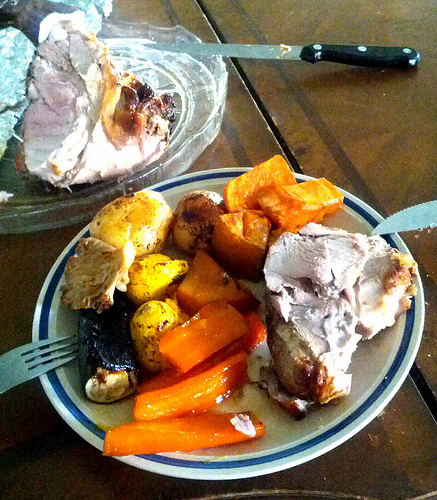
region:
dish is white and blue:
[15, 150, 433, 485]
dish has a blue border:
[26, 159, 435, 487]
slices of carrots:
[102, 304, 269, 458]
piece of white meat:
[252, 223, 413, 415]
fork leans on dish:
[5, 323, 81, 398]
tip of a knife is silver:
[369, 197, 435, 248]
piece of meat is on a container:
[0, 65, 227, 204]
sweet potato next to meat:
[206, 157, 341, 251]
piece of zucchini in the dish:
[67, 312, 146, 411]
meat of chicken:
[255, 217, 424, 419]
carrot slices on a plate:
[101, 306, 265, 463]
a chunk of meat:
[259, 220, 412, 410]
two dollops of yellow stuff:
[127, 250, 188, 359]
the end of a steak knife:
[363, 190, 434, 243]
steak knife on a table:
[139, 37, 423, 72]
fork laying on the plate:
[0, 324, 87, 391]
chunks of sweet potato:
[220, 148, 343, 253]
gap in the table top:
[232, 63, 291, 152]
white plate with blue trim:
[21, 166, 424, 480]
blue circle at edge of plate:
[26, 165, 423, 480]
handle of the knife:
[347, 39, 415, 79]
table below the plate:
[375, 431, 419, 464]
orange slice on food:
[154, 401, 227, 455]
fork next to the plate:
[29, 320, 95, 378]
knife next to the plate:
[347, 183, 420, 246]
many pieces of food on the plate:
[77, 168, 386, 375]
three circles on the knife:
[306, 31, 418, 79]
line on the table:
[399, 360, 432, 421]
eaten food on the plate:
[30, 12, 187, 155]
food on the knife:
[266, 33, 297, 69]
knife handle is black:
[292, 26, 431, 87]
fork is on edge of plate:
[0, 284, 102, 407]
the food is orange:
[154, 244, 251, 481]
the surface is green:
[1, 0, 432, 496]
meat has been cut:
[72, 284, 145, 408]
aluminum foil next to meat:
[2, 20, 53, 160]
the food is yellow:
[115, 252, 202, 375]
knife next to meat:
[350, 181, 434, 250]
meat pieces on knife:
[242, 32, 303, 73]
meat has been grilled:
[68, 312, 147, 395]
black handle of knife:
[300, 26, 417, 75]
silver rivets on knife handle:
[301, 29, 411, 55]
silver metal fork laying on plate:
[0, 325, 73, 395]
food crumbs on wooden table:
[413, 226, 436, 255]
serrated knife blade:
[367, 190, 435, 239]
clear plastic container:
[177, 59, 225, 142]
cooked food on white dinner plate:
[48, 170, 410, 449]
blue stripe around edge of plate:
[278, 430, 325, 458]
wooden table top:
[321, 80, 433, 153]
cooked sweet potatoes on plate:
[137, 248, 257, 454]